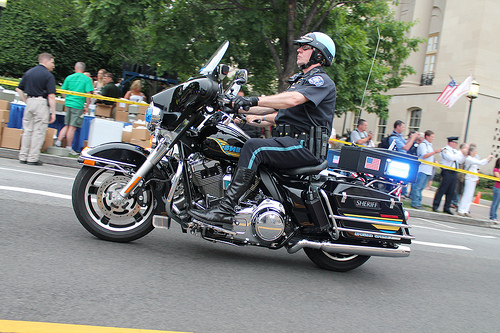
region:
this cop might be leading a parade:
[30, 14, 492, 263]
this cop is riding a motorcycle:
[64, 28, 425, 270]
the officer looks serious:
[218, 23, 347, 242]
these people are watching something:
[350, 95, 498, 186]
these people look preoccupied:
[25, 41, 152, 168]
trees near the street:
[5, 1, 431, 110]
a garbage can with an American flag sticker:
[335, 133, 422, 174]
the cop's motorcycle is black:
[83, 85, 430, 233]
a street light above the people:
[450, 75, 488, 165]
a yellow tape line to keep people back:
[6, 71, 497, 195]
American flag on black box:
[362, 151, 382, 176]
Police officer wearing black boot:
[186, 27, 336, 230]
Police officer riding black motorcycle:
[185, 22, 335, 228]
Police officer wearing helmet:
[184, 28, 337, 230]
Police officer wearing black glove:
[185, 29, 335, 228]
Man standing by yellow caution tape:
[14, 50, 59, 169]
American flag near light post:
[432, 73, 459, 112]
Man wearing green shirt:
[49, 55, 95, 154]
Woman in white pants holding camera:
[455, 145, 490, 221]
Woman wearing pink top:
[485, 153, 498, 225]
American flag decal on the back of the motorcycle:
[363, 156, 381, 171]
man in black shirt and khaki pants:
[16, 50, 57, 165]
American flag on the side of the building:
[435, 73, 460, 106]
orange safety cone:
[475, 190, 480, 205]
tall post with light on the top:
[462, 78, 479, 143]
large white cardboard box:
[86, 117, 121, 146]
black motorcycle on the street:
[71, 37, 413, 271]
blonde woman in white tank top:
[123, 79, 146, 104]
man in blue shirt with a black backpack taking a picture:
[377, 118, 418, 154]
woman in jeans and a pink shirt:
[488, 156, 498, 223]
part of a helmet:
[310, 13, 331, 53]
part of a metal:
[339, 226, 385, 263]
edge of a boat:
[202, 210, 230, 240]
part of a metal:
[348, 238, 385, 273]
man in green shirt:
[63, 56, 90, 155]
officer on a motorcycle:
[78, 39, 403, 272]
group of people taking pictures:
[391, 115, 488, 214]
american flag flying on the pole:
[435, 73, 463, 114]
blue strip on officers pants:
[244, 135, 302, 166]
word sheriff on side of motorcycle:
[352, 193, 384, 214]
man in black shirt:
[10, 47, 59, 169]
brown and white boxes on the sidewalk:
[96, 106, 155, 133]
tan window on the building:
[421, 22, 446, 95]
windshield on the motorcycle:
[192, 38, 229, 86]